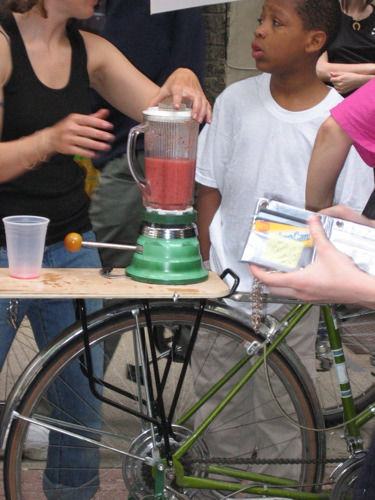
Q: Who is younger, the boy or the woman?
A: The boy is younger than the woman.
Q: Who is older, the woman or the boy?
A: The woman is older than the boy.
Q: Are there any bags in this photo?
A: No, there are no bags.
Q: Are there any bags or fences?
A: No, there are no bags or fences.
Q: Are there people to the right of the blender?
A: Yes, there is a person to the right of the blender.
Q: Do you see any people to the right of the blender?
A: Yes, there is a person to the right of the blender.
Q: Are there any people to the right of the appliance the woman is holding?
A: Yes, there is a person to the right of the blender.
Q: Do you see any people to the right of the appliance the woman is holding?
A: Yes, there is a person to the right of the blender.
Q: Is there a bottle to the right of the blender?
A: No, there is a person to the right of the blender.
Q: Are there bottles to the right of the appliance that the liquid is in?
A: No, there is a person to the right of the blender.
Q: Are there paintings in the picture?
A: No, there are no paintings.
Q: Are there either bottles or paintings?
A: No, there are no paintings or bottles.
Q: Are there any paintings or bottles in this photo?
A: No, there are no paintings or bottles.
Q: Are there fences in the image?
A: No, there are no fences.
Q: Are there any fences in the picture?
A: No, there are no fences.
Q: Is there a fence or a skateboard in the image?
A: No, there are no fences or skateboards.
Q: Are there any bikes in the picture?
A: Yes, there is a bike.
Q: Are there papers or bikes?
A: Yes, there is a bike.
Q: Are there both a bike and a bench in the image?
A: No, there is a bike but no benches.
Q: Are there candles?
A: No, there are no candles.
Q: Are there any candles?
A: No, there are no candles.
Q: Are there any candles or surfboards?
A: No, there are no candles or surfboards.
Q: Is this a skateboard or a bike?
A: This is a bike.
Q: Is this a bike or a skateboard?
A: This is a bike.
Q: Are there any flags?
A: No, there are no flags.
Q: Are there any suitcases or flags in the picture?
A: No, there are no flags or suitcases.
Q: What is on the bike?
A: The chain is on the bike.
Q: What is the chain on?
A: The chain is on the bike.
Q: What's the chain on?
A: The chain is on the bike.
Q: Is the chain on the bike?
A: Yes, the chain is on the bike.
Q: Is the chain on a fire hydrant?
A: No, the chain is on the bike.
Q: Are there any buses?
A: No, there are no buses.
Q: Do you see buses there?
A: No, there are no buses.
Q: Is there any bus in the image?
A: No, there are no buses.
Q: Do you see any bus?
A: No, there are no buses.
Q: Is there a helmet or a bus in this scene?
A: No, there are no buses or helmets.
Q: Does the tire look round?
A: Yes, the tire is round.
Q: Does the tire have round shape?
A: Yes, the tire is round.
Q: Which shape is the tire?
A: The tire is round.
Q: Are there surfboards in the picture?
A: No, there are no surfboards.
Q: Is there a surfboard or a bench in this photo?
A: No, there are no surfboards or benches.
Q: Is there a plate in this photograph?
A: No, there are no plates.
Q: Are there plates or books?
A: No, there are no plates or books.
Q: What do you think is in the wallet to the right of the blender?
A: The card is in the wallet.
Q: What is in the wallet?
A: The card is in the wallet.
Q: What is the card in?
A: The card is in the wallet.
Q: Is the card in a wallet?
A: Yes, the card is in a wallet.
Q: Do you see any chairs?
A: No, there are no chairs.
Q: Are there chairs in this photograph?
A: No, there are no chairs.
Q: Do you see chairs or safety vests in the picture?
A: No, there are no chairs or safety vests.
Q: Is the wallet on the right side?
A: Yes, the wallet is on the right of the image.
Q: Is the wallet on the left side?
A: No, the wallet is on the right of the image.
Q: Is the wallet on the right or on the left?
A: The wallet is on the right of the image.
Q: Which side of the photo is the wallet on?
A: The wallet is on the right of the image.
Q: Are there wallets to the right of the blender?
A: Yes, there is a wallet to the right of the blender.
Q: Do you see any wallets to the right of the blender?
A: Yes, there is a wallet to the right of the blender.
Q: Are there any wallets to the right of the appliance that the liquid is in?
A: Yes, there is a wallet to the right of the blender.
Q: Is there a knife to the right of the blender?
A: No, there is a wallet to the right of the blender.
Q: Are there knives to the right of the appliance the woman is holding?
A: No, there is a wallet to the right of the blender.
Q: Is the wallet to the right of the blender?
A: Yes, the wallet is to the right of the blender.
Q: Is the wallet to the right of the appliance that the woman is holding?
A: Yes, the wallet is to the right of the blender.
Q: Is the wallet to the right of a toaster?
A: No, the wallet is to the right of the blender.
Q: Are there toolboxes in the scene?
A: No, there are no toolboxes.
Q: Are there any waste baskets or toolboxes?
A: No, there are no toolboxes or waste baskets.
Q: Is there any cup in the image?
A: Yes, there is a cup.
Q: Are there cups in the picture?
A: Yes, there is a cup.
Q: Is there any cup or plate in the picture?
A: Yes, there is a cup.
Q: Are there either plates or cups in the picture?
A: Yes, there is a cup.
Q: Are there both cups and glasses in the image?
A: No, there is a cup but no glasses.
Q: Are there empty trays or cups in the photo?
A: Yes, there is an empty cup.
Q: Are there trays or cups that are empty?
A: Yes, the cup is empty.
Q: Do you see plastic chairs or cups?
A: Yes, there is a plastic cup.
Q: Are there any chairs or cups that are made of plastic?
A: Yes, the cup is made of plastic.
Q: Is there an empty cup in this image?
A: Yes, there is an empty cup.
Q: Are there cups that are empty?
A: Yes, there is a cup that is empty.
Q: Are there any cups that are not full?
A: Yes, there is a empty cup.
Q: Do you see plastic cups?
A: Yes, there is a cup that is made of plastic.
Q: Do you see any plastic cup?
A: Yes, there is a cup that is made of plastic.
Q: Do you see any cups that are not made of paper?
A: Yes, there is a cup that is made of plastic.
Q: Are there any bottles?
A: No, there are no bottles.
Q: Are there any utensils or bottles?
A: No, there are no bottles or utensils.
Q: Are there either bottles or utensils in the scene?
A: No, there are no bottles or utensils.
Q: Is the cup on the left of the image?
A: Yes, the cup is on the left of the image.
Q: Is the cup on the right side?
A: No, the cup is on the left of the image.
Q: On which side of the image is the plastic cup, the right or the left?
A: The cup is on the left of the image.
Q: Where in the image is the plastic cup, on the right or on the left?
A: The cup is on the left of the image.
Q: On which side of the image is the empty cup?
A: The cup is on the left of the image.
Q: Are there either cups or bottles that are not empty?
A: No, there is a cup but it is empty.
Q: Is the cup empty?
A: Yes, the cup is empty.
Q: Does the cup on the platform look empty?
A: Yes, the cup is empty.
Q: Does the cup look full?
A: No, the cup is empty.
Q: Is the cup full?
A: No, the cup is empty.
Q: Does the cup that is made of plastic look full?
A: No, the cup is empty.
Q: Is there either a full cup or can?
A: No, there is a cup but it is empty.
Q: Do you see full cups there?
A: No, there is a cup but it is empty.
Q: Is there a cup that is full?
A: No, there is a cup but it is empty.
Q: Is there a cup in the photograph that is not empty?
A: No, there is a cup but it is empty.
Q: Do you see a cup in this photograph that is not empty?
A: No, there is a cup but it is empty.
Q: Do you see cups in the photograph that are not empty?
A: No, there is a cup but it is empty.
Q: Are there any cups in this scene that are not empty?
A: No, there is a cup but it is empty.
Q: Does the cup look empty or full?
A: The cup is empty.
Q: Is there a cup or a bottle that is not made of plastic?
A: No, there is a cup but it is made of plastic.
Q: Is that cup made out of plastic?
A: Yes, the cup is made of plastic.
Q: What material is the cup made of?
A: The cup is made of plastic.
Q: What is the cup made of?
A: The cup is made of plastic.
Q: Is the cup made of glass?
A: No, the cup is made of plastic.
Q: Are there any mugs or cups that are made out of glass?
A: No, there is a cup but it is made of plastic.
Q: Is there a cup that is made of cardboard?
A: No, there is a cup but it is made of plastic.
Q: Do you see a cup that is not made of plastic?
A: No, there is a cup but it is made of plastic.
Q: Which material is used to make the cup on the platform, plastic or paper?
A: The cup is made of plastic.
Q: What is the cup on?
A: The cup is on the platform.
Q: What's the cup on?
A: The cup is on the platform.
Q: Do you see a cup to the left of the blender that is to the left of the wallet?
A: Yes, there is a cup to the left of the blender.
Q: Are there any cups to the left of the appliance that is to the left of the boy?
A: Yes, there is a cup to the left of the blender.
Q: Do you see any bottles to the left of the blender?
A: No, there is a cup to the left of the blender.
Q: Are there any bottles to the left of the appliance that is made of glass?
A: No, there is a cup to the left of the blender.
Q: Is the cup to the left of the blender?
A: Yes, the cup is to the left of the blender.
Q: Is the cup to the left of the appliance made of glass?
A: Yes, the cup is to the left of the blender.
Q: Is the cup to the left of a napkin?
A: No, the cup is to the left of the blender.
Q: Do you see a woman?
A: Yes, there is a woman.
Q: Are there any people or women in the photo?
A: Yes, there is a woman.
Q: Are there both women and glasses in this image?
A: No, there is a woman but no glasses.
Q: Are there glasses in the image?
A: No, there are no glasses.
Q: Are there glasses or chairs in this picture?
A: No, there are no glasses or chairs.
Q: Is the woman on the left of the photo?
A: Yes, the woman is on the left of the image.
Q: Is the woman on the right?
A: No, the woman is on the left of the image.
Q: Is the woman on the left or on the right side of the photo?
A: The woman is on the left of the image.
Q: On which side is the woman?
A: The woman is on the left of the image.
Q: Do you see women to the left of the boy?
A: Yes, there is a woman to the left of the boy.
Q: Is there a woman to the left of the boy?
A: Yes, there is a woman to the left of the boy.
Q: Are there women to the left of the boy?
A: Yes, there is a woman to the left of the boy.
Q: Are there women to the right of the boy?
A: No, the woman is to the left of the boy.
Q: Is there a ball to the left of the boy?
A: No, there is a woman to the left of the boy.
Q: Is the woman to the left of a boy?
A: Yes, the woman is to the left of a boy.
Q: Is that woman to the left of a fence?
A: No, the woman is to the left of a boy.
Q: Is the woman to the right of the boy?
A: No, the woman is to the left of the boy.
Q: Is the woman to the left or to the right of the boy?
A: The woman is to the left of the boy.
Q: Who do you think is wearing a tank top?
A: The woman is wearing a tank top.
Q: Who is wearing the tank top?
A: The woman is wearing a tank top.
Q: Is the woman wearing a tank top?
A: Yes, the woman is wearing a tank top.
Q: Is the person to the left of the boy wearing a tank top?
A: Yes, the woman is wearing a tank top.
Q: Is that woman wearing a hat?
A: No, the woman is wearing a tank top.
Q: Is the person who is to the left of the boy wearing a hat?
A: No, the woman is wearing a tank top.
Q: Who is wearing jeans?
A: The woman is wearing jeans.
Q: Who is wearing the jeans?
A: The woman is wearing jeans.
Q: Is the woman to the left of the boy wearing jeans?
A: Yes, the woman is wearing jeans.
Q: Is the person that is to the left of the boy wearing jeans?
A: Yes, the woman is wearing jeans.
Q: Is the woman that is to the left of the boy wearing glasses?
A: No, the woman is wearing jeans.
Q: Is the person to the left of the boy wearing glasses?
A: No, the woman is wearing jeans.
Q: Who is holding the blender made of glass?
A: The woman is holding the blender.